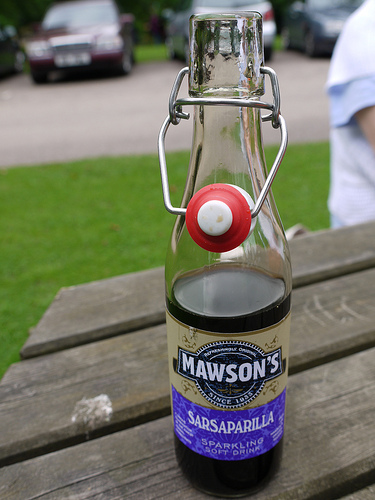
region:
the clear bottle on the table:
[158, 10, 292, 496]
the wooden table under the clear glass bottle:
[0, 218, 374, 496]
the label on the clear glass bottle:
[164, 305, 289, 460]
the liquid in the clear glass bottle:
[164, 263, 292, 497]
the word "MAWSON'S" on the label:
[181, 351, 277, 382]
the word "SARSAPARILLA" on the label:
[187, 410, 274, 433]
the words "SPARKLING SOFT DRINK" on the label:
[200, 437, 264, 455]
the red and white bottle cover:
[186, 182, 258, 252]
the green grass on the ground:
[0, 140, 331, 380]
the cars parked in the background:
[0, 0, 374, 84]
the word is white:
[184, 345, 280, 386]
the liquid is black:
[250, 316, 268, 329]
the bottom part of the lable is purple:
[173, 397, 186, 415]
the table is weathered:
[309, 383, 345, 435]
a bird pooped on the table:
[65, 392, 117, 431]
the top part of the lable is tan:
[264, 338, 284, 350]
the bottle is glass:
[209, 266, 252, 297]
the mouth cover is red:
[213, 183, 240, 205]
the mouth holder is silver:
[193, 91, 256, 114]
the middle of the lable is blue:
[194, 338, 276, 402]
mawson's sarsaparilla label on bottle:
[141, 309, 311, 476]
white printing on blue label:
[168, 376, 305, 472]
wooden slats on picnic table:
[18, 271, 365, 483]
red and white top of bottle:
[135, 140, 297, 291]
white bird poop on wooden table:
[62, 384, 122, 439]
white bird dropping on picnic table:
[56, 382, 129, 439]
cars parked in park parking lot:
[13, 3, 308, 105]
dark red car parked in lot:
[12, 3, 171, 96]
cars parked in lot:
[24, 4, 303, 97]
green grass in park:
[36, 188, 129, 258]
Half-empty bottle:
[154, 5, 294, 498]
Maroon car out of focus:
[22, 0, 136, 90]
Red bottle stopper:
[183, 182, 251, 252]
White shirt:
[327, 0, 373, 233]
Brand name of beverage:
[176, 346, 277, 382]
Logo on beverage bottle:
[171, 338, 285, 409]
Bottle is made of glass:
[156, 0, 296, 495]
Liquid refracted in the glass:
[169, 257, 286, 319]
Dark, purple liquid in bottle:
[159, 258, 297, 496]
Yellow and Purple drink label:
[164, 309, 288, 461]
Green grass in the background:
[0, 173, 155, 260]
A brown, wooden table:
[1, 276, 154, 498]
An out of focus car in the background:
[19, 0, 140, 88]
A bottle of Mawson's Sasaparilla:
[159, 2, 296, 498]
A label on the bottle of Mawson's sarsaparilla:
[166, 310, 287, 458]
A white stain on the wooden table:
[64, 391, 115, 440]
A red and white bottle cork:
[181, 174, 257, 253]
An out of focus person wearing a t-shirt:
[330, 5, 372, 220]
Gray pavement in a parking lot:
[0, 88, 148, 146]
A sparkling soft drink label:
[196, 434, 264, 460]